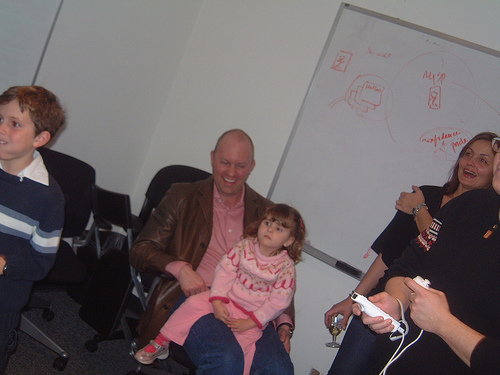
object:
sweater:
[208, 235, 297, 329]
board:
[265, 2, 499, 281]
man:
[351, 136, 500, 375]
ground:
[407, 203, 456, 260]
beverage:
[329, 326, 341, 335]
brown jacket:
[128, 175, 295, 349]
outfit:
[160, 236, 297, 375]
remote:
[350, 292, 401, 334]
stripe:
[0, 205, 61, 255]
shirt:
[17, 148, 49, 186]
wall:
[218, 1, 497, 281]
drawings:
[328, 34, 472, 162]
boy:
[0, 85, 67, 368]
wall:
[62, 19, 299, 139]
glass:
[325, 316, 342, 348]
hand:
[324, 299, 353, 331]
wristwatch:
[289, 327, 292, 338]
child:
[133, 203, 307, 375]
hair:
[240, 203, 306, 261]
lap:
[224, 331, 264, 348]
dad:
[129, 128, 296, 375]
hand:
[351, 291, 406, 334]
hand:
[403, 276, 451, 333]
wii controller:
[413, 275, 432, 290]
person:
[321, 132, 500, 375]